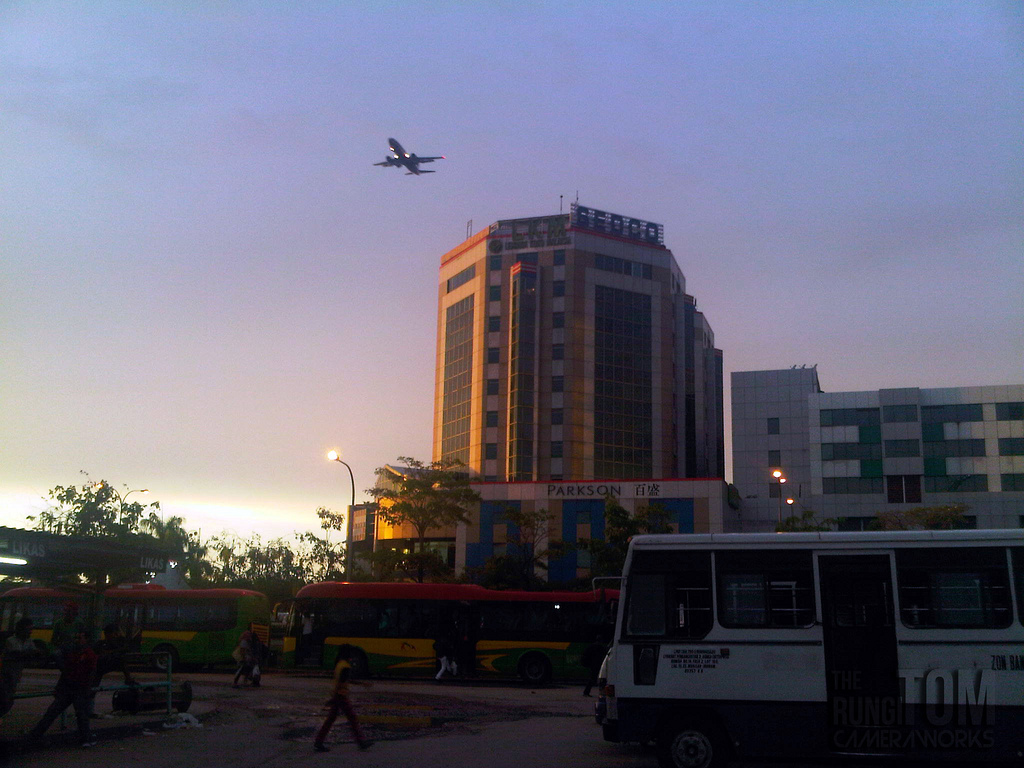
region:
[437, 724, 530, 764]
the street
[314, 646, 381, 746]
a person walking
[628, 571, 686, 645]
a window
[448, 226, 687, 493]
a tall building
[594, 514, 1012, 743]
a bus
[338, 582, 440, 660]
a yellow and red bus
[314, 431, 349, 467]
a street light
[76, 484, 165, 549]
the leaves are green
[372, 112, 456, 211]
Jumbo jet is flying in the sky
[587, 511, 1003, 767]
White and black bus is driving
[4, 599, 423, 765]
People are walking about on the street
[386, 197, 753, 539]
Red and white building with blue logo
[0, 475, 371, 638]
Trees against the backdrop of sunset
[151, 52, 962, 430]
Sky is colored from sunset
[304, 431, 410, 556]
Streetlamps are illuminated in the night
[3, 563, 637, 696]
Red gold and green busses in a row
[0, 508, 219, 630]
A train station with blue logo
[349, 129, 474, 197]
plane in the sky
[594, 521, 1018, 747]
shuttle bus is white in color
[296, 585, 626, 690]
bus is red, green and yellow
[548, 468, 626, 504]
building has letters on it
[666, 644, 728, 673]
writing on side of bus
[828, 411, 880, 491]
windows on building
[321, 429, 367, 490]
street lamp on a pole